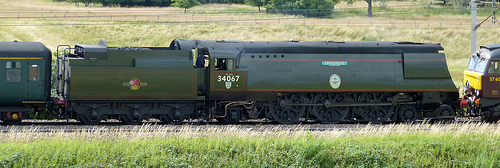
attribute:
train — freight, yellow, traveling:
[6, 35, 481, 122]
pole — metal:
[467, 2, 479, 57]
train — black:
[0, 40, 495, 120]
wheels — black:
[4, 90, 456, 125]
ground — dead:
[402, 110, 426, 142]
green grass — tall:
[18, 119, 493, 164]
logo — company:
[113, 65, 155, 107]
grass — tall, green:
[0, 132, 498, 166]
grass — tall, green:
[3, 2, 497, 81]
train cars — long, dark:
[9, 39, 498, 113]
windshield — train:
[466, 55, 486, 72]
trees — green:
[254, 0, 341, 20]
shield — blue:
[223, 78, 231, 91]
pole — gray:
[436, 40, 496, 119]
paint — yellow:
[463, 69, 481, 91]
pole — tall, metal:
[466, 0, 498, 55]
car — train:
[55, 42, 455, 114]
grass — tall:
[27, 122, 484, 137]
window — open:
[4, 61, 17, 79]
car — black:
[0, 43, 50, 110]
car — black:
[61, 42, 453, 107]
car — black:
[457, 47, 484, 103]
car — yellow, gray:
[461, 35, 484, 102]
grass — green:
[50, 0, 476, 43]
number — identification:
[212, 69, 241, 90]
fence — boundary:
[158, 0, 465, 28]